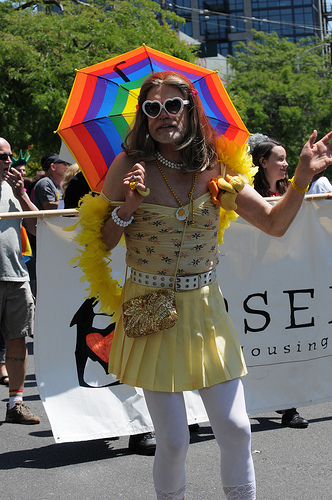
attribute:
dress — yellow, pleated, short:
[91, 161, 248, 393]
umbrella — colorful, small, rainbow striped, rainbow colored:
[53, 43, 251, 196]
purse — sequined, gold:
[122, 286, 179, 337]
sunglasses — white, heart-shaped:
[140, 96, 191, 120]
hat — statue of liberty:
[10, 145, 33, 166]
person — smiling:
[248, 138, 289, 198]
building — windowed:
[34, 0, 331, 105]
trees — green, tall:
[2, 3, 212, 180]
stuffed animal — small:
[206, 171, 244, 212]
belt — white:
[129, 268, 216, 291]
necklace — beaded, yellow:
[150, 158, 198, 226]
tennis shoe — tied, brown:
[4, 400, 41, 426]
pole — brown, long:
[0, 191, 331, 220]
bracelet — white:
[152, 151, 192, 173]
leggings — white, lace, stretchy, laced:
[139, 375, 261, 499]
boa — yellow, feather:
[71, 190, 127, 324]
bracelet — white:
[108, 206, 134, 231]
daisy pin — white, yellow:
[173, 205, 189, 226]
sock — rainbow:
[7, 386, 26, 409]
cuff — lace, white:
[221, 484, 257, 499]